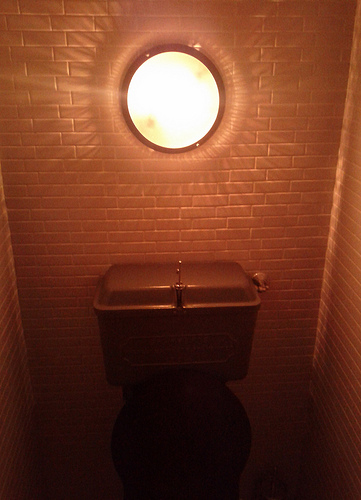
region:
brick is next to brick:
[60, 183, 107, 197]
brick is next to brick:
[104, 208, 143, 220]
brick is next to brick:
[178, 206, 217, 218]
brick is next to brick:
[225, 215, 262, 229]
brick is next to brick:
[250, 249, 285, 259]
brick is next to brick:
[24, 62, 67, 76]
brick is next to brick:
[269, 90, 310, 103]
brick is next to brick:
[92, 15, 137, 31]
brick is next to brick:
[177, 14, 232, 32]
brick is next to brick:
[288, 280, 322, 292]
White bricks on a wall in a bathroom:
[12, 151, 62, 172]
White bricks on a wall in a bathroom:
[88, 179, 134, 195]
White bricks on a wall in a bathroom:
[135, 181, 189, 202]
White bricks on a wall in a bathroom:
[165, 215, 189, 224]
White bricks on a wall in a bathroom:
[176, 217, 234, 235]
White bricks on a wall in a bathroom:
[226, 212, 282, 249]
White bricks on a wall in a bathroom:
[261, 255, 301, 282]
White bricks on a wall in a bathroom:
[263, 309, 293, 332]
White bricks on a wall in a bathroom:
[252, 333, 300, 366]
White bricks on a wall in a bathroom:
[248, 363, 300, 389]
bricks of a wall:
[25, 86, 76, 109]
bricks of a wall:
[30, 141, 88, 164]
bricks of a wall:
[17, 26, 73, 51]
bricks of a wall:
[226, 28, 277, 58]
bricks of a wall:
[213, 153, 263, 174]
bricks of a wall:
[220, 187, 276, 211]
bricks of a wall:
[271, 57, 325, 82]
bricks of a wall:
[259, 185, 305, 206]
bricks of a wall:
[258, 230, 300, 255]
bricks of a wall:
[287, 251, 323, 273]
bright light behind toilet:
[119, 53, 229, 164]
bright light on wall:
[112, 38, 242, 160]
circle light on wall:
[102, 45, 235, 168]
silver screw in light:
[143, 50, 154, 60]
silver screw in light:
[193, 138, 209, 150]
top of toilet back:
[103, 251, 264, 309]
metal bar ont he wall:
[234, 276, 269, 306]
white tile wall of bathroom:
[82, 169, 224, 239]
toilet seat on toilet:
[109, 382, 246, 498]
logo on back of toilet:
[118, 332, 239, 376]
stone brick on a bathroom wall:
[190, 192, 232, 210]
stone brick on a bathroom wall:
[175, 202, 215, 221]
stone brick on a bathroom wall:
[214, 201, 252, 221]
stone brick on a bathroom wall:
[249, 202, 289, 217]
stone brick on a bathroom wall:
[285, 199, 322, 216]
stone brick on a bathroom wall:
[115, 193, 159, 211]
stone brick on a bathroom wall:
[77, 195, 119, 209]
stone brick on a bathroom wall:
[39, 194, 80, 208]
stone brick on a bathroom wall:
[40, 218, 83, 233]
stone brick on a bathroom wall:
[77, 217, 120, 232]